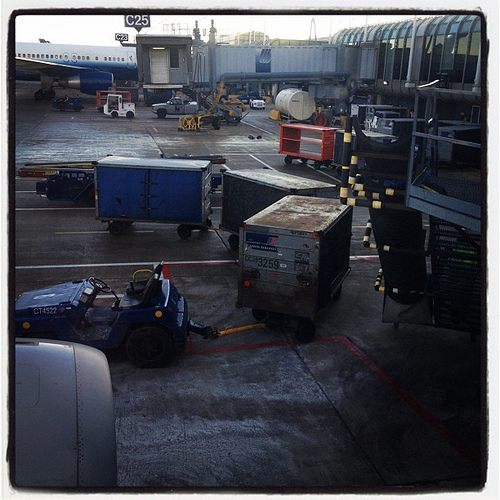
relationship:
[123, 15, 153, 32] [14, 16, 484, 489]
sign at airport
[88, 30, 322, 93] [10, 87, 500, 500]
jetway on ground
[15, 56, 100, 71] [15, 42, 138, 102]
wing on plane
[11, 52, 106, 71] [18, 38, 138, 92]
wing on an airplane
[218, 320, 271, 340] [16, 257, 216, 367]
tow bar on cart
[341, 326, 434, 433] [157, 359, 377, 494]
red line on ground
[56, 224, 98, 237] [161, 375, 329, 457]
yellow line on ground